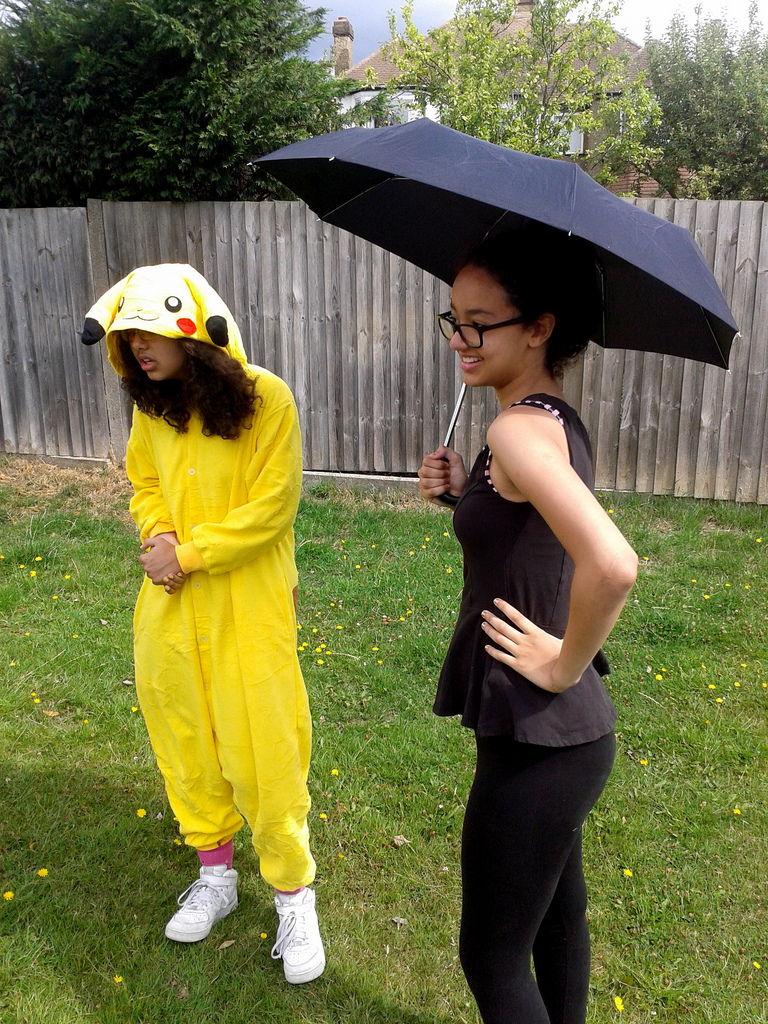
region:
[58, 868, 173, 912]
the grass is green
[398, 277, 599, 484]
the girl is wearing glasses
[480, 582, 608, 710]
woman with her hand on her hip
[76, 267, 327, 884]
girl wearing a yellow one-piece outfit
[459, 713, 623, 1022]
woman wearing black leggings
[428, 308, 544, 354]
dark-rimmed glasses on a woman's face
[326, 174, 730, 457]
woman holding black umbrella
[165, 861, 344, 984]
white tennis shoes with long laces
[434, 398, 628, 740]
a black tank top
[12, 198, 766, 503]
a faded wooden fence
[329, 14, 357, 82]
a chimney on a building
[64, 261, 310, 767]
Girl wearing Pokeman costume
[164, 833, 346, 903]
She has bright pink socks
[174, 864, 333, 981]
White sneakers worn by girl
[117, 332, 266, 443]
Curly long dark hair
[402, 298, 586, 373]
She is wearing eyeglasse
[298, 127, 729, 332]
Black umbrella for shade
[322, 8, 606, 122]
Chimney on house in background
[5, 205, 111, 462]
Tall wooden privacy fence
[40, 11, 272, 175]
Green bush against fence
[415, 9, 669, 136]
Tree with buds blooming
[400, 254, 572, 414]
A girl has black eyeglasses on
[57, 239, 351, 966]
A girl is wearing a Pokemon costume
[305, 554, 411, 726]
Yellow dandelions are on the grass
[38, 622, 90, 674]
The grass is green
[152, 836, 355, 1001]
A girl has on white sneakers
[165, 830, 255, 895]
Pink socks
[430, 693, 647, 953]
Black pants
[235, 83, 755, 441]
A black umbrella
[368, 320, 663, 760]
A girl has her hand on her hip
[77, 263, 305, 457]
A girl has brown curly hair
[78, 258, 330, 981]
young adult wearing pokemon pjs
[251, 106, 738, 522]
a girl holding a black umbrella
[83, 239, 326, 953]
Girl in a pikachu jumpsuit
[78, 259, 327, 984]
Girl in Pikachu costume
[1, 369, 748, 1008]
it is daytime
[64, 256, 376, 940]
A girl dressed in yellow.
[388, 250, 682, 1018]
A girl dressed in black.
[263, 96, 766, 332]
A black umbrella.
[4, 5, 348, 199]
A green tree in the background.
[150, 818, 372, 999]
Girl on the left wearing white tennis shoes.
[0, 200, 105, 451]
A wooden fence in back of yard.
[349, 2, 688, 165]
Roof of a house in background.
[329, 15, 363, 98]
Chimney on roof of house.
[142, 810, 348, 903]
the girl has on pink socks.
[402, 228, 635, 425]
The girl has on black glasses.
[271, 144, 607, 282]
girl has black umbrella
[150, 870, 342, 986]
She is wearing white sneakers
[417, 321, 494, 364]
The girl wears glasses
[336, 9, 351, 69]
there is a chimney on the house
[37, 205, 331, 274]
the fence is made of wood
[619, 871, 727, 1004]
the grass is green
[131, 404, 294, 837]
she is wearing a yellow suit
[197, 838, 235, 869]
she has pink socks on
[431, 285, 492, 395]
the girl is smiling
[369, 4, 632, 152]
there is a house in the background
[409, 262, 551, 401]
woman is wearing glasses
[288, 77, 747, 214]
a black umbrella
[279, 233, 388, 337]
a grey fence is behind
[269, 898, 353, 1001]
woman wearing sneakers